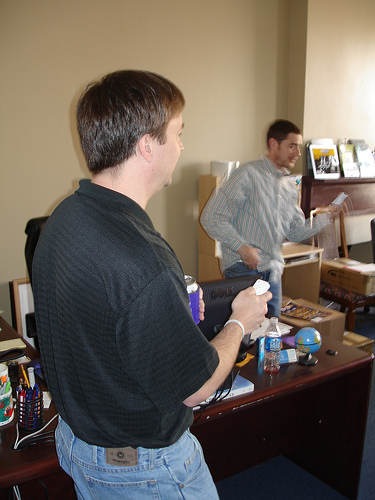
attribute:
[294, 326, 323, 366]
globe — blue, small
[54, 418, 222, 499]
pants — blue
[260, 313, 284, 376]
bottle — plastic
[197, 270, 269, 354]
monitor — black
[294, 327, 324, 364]
globe — small, blue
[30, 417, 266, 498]
jeans — light blue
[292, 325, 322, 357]
globe — small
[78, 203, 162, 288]
shirt — black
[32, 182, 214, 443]
shirt — black, collared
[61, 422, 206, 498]
blue jeans — light colored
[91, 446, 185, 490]
jeans — light blue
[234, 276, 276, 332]
controller — small, white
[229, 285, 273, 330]
hand — white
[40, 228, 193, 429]
shirt — black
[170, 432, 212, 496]
pocket — small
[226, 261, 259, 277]
pocket — small